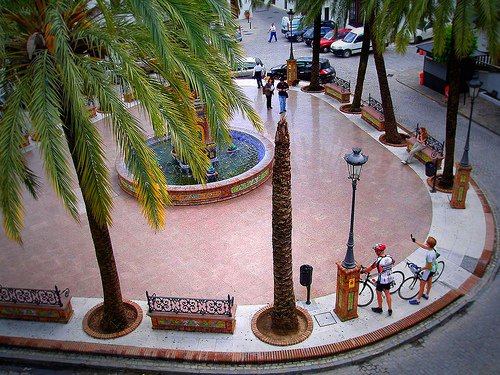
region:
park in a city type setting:
[5, 48, 484, 349]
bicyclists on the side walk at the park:
[357, 209, 495, 319]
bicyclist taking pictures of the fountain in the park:
[399, 208, 456, 320]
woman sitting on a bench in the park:
[386, 93, 491, 222]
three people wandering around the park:
[241, 54, 358, 161]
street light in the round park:
[311, 122, 379, 339]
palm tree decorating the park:
[18, 74, 200, 354]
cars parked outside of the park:
[239, 6, 379, 100]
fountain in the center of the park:
[107, 58, 304, 223]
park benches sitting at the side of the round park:
[3, 227, 248, 347]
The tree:
[17, 25, 194, 258]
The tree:
[15, 42, 270, 339]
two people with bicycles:
[349, 232, 448, 317]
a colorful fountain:
[116, 126, 273, 205]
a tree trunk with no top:
[266, 114, 300, 336]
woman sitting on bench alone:
[400, 126, 445, 176]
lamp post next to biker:
[334, 146, 369, 320]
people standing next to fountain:
[258, 74, 290, 114]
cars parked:
[275, 3, 384, 61]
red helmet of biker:
[373, 242, 386, 256]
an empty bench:
[141, 289, 241, 334]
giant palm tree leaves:
[0, 1, 267, 240]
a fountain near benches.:
[125, 98, 282, 211]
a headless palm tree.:
[255, 78, 308, 344]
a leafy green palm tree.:
[4, 1, 246, 335]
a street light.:
[310, 136, 377, 326]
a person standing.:
[373, 240, 396, 325]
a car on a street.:
[325, 23, 396, 67]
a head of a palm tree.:
[19, 17, 93, 68]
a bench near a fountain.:
[118, 277, 249, 329]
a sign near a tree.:
[297, 262, 324, 307]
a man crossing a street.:
[265, 13, 285, 52]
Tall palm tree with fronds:
[5, 2, 245, 349]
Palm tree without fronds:
[251, 99, 327, 351]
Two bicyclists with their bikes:
[341, 225, 456, 325]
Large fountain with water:
[88, 89, 277, 217]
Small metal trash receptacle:
[295, 261, 315, 306]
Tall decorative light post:
[332, 142, 369, 334]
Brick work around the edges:
[79, 335, 332, 372]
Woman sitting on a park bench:
[384, 116, 449, 176]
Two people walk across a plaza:
[254, 74, 303, 116]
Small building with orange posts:
[410, 35, 481, 104]